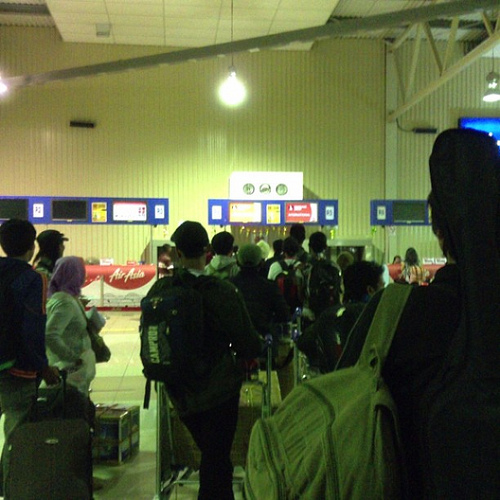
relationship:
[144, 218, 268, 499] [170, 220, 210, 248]
man wearing black cap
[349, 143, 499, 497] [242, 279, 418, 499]
person holding backpack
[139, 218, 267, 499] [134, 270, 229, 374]
man has backpack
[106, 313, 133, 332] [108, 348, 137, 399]
floor covered in tiles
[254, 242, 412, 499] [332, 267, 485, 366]
backpack over shoulder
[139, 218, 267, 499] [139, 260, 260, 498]
man in clothes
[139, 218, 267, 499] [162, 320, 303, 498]
man in back of luggage cart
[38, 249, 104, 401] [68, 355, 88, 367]
woman with hand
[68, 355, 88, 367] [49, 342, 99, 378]
hand on hip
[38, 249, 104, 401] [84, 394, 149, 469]
woman next to box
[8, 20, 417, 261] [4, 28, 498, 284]
lines across wall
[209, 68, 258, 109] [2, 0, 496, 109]
light under supporting beam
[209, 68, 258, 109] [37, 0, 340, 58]
light under ceiling panel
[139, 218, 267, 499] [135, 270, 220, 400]
man carrying backpack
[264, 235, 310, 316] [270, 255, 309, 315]
person with backpack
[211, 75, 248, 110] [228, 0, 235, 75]
bright light hanging on wire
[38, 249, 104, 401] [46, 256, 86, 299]
woman with headscarf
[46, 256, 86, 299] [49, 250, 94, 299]
headscarf on head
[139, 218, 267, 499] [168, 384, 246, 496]
man with legs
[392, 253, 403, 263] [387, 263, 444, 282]
person separated by counter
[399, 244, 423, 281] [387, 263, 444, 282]
person separated by counter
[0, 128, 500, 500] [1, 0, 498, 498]
people at airport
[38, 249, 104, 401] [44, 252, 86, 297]
woman wearing headscarf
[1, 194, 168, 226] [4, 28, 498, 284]
electronic sign hanging on wall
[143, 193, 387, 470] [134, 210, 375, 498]
people in line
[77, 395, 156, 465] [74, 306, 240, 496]
boxes on floor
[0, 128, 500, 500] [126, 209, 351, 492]
people in line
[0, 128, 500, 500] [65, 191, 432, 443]
people waiting in line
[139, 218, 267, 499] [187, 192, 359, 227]
man waiting in line for tickets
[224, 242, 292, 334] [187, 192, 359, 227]
person waiting in line for tickets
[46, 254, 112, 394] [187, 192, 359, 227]
person waiting in line for tickets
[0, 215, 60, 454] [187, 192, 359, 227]
man waiting in line for tickets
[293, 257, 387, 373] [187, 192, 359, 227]
person waiting in line for tickets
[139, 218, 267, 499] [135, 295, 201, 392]
man wearing backpack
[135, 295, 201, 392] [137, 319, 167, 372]
backpack with writing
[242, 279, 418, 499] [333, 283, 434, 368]
backpack on person's shoulder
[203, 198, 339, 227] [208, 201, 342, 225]
sign with background